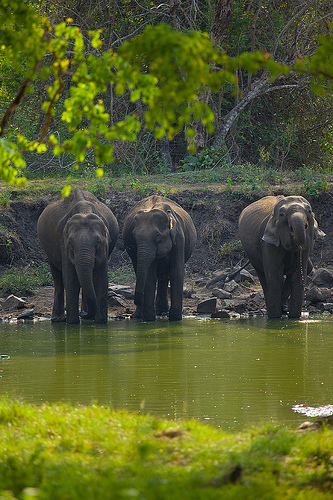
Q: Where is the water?
A: In front of the elephants.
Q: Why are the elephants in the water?
A: Drinking water.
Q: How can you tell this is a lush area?
A: Green trees.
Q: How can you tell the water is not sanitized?
A: The color.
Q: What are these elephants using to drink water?
A: The trunk.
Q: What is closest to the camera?
A: Tree.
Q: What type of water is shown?
A: Fresh water.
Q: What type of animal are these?
A: Elephants.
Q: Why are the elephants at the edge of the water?
A: To drink.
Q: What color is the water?
A: Green.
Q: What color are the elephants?
A: Gray.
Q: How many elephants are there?
A: Three.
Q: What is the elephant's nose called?
A: Trunk.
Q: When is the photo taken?
A: Daytime.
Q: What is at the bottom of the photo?
A: Grass.